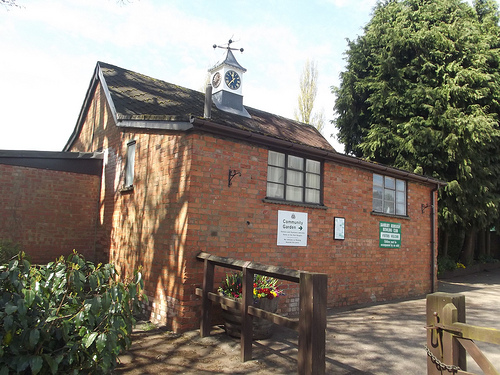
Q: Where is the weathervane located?
A: Above clock.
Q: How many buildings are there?
A: 1.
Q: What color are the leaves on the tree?
A: Green.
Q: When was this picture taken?
A: Daytime.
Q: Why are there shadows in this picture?
A: It's sunny.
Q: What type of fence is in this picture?
A: Wooden.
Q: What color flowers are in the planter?
A: Red and yellow.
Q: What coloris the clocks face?
A: Blue.